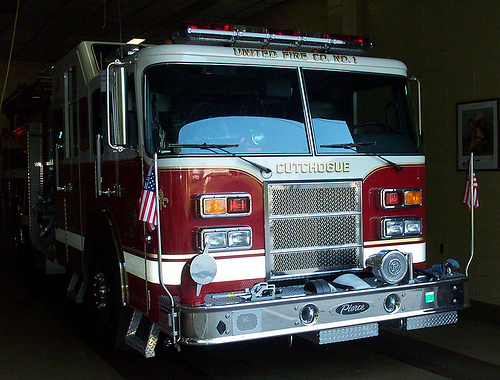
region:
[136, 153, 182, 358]
Small american flag on truck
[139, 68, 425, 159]
Reflective window on truck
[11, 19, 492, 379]
Bright red fire truck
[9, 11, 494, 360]
Red fire truck sitting in garage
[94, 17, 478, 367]
Fire truck of United Fire Co. No. 1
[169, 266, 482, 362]
Metallic silver truck bumper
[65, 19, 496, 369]
Fire truck with two american flags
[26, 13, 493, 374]
Clean fire truck parked in garage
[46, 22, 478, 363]
Fire truck ready to respond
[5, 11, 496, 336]
Clean and shiny bright red fire truck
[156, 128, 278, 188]
windshield wiper on front of fire truck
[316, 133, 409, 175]
windshield wiper on front of frietruck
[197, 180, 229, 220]
yellow signal light on front of fire truck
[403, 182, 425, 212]
yellow signal light on front of fire truck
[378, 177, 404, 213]
red light on front of fire truck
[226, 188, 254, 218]
red light on front of fire truck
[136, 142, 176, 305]
American flag on front of fire truck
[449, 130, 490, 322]
American flag on front of fire truck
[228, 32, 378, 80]
name of fire engine company on front of truck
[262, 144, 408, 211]
name of fire engine company on front of truck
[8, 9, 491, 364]
a firetruck in a fire station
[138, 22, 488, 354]
the front of a fire truck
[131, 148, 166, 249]
the American flag on a firetruck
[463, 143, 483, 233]
the American flag on a firetruck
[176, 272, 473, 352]
the bumper of a firetruck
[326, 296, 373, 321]
the company that built the firetruck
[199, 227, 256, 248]
the headlights of a firetruck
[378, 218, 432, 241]
the headlights of a firetruck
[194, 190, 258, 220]
the turning signals of a firetruck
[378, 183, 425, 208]
the turning signals of a firetruck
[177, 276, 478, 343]
BUMPER OF FIRE TRUCK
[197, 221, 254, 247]
FRONT HEADLIGHTS OF TRUCK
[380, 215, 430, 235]
FRONT HEADLIGHTS OF TRUCK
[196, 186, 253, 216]
FLASHING LIGHTS FOR TRUCK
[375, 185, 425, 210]
FLASHING LIGHTS FOR TRUCK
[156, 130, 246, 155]
WINDSHIELD WIPER FOR FIRE TRUCK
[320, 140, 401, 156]
WINDSHIELD WIPER FOR FIRE TRUCK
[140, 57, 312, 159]
FRONT WINDSHIELD FOR FIRE TRUCK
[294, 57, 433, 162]
FRONT WINDSHIELD FOR FIRE TRUCK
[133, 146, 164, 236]
AMERICAN FLAG ON FIRE TRUCK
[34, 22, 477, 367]
the front of a fire engine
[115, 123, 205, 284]
an american flag on the left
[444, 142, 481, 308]
an american flag on the right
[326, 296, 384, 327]
Pierce on the front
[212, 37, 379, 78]
gold letters on the top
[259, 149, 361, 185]
Cutchosue on the front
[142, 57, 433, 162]
two windows on the front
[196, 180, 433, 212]
red and orange lights on front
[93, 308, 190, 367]
a silver metal step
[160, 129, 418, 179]
two wiper blades on front